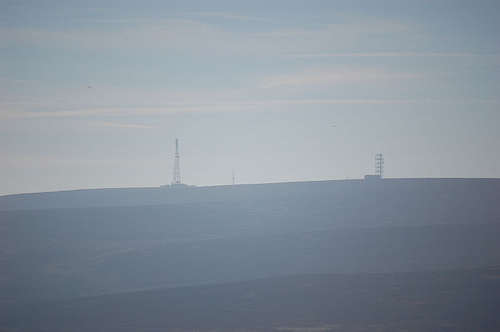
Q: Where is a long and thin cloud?
A: Above towers.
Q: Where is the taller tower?
A: Left.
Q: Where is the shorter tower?
A: On the right.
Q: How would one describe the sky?
A: Light thin clouds.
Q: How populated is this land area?
A: Sparsely.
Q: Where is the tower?
A: In the horizon.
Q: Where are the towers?
A: On the hill.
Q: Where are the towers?
A: On the mountain.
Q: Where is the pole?
A: Between towers.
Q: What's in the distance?
A: Power poles.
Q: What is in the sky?
A: Clouds.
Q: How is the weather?
A: Hazy.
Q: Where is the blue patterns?
A: In sky.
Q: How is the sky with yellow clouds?
A: Foggy.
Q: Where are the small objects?
A: In horizon.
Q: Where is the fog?
A: Over water.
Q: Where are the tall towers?
A: Background.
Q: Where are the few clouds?
A: Sky.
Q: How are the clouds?
A: Long.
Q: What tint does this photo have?
A: Light blue.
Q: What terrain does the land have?
A: It's hilly.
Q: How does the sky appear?
A: Hazy.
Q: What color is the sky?
A: Light blue.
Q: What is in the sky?
A: Clouds.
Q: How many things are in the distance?
A: Two.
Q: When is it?
A: Day time.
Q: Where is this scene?
A: Oil rig site.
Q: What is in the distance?
A: An oil rig.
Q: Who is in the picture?
A: No one.